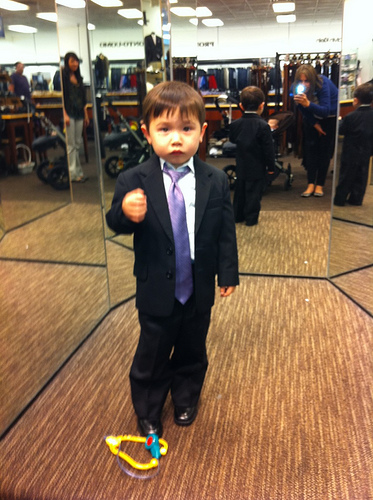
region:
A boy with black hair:
[133, 76, 219, 171]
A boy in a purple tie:
[151, 153, 206, 310]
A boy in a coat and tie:
[102, 89, 251, 314]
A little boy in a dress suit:
[97, 77, 243, 428]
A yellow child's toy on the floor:
[88, 421, 183, 478]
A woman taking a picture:
[283, 56, 330, 123]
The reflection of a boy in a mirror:
[222, 80, 282, 239]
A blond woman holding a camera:
[279, 58, 326, 103]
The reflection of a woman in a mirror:
[56, 48, 95, 135]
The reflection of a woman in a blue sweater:
[282, 59, 340, 136]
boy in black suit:
[112, 75, 251, 431]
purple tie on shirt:
[163, 164, 192, 305]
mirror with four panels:
[2, 30, 371, 371]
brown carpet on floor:
[36, 282, 365, 497]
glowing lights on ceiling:
[270, 0, 301, 26]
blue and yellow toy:
[99, 432, 173, 470]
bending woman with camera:
[286, 66, 338, 199]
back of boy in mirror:
[229, 90, 271, 220]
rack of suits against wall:
[192, 62, 265, 91]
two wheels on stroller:
[36, 161, 67, 189]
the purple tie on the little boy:
[165, 171, 197, 306]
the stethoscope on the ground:
[101, 435, 170, 470]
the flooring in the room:
[6, 250, 371, 498]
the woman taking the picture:
[284, 67, 340, 201]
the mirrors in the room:
[16, 6, 372, 422]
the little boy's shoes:
[142, 398, 208, 433]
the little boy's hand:
[127, 186, 150, 223]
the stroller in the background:
[98, 100, 151, 176]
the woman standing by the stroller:
[64, 54, 99, 188]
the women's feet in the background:
[302, 184, 321, 203]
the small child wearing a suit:
[105, 81, 238, 437]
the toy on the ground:
[105, 434, 166, 479]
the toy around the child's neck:
[162, 166, 192, 304]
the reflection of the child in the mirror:
[229, 84, 273, 226]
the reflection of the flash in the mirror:
[296, 83, 305, 92]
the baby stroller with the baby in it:
[215, 94, 293, 190]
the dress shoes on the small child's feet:
[137, 402, 197, 435]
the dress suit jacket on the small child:
[104, 151, 239, 315]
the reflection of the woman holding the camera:
[289, 64, 335, 194]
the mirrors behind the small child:
[1, 0, 371, 441]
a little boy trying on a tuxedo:
[107, 72, 260, 378]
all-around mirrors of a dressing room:
[2, 1, 362, 200]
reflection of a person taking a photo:
[284, 57, 333, 204]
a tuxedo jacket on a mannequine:
[139, 23, 171, 66]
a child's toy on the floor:
[88, 417, 181, 485]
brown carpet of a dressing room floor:
[246, 305, 345, 453]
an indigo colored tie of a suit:
[160, 167, 202, 315]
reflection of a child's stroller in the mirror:
[95, 90, 146, 170]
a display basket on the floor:
[13, 142, 39, 177]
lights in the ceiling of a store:
[265, 0, 310, 37]